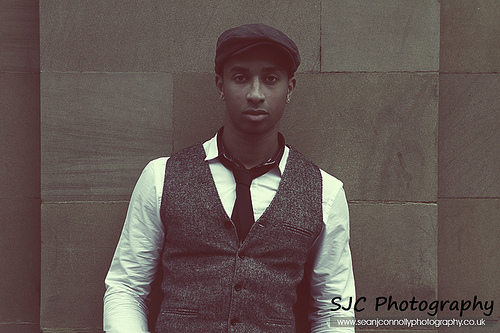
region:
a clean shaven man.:
[181, 13, 323, 163]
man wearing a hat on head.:
[195, 10, 305, 140]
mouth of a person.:
[241, 101, 268, 132]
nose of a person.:
[245, 75, 265, 105]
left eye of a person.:
[260, 70, 280, 95]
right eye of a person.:
[230, 65, 250, 86]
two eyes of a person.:
[225, 67, 285, 83]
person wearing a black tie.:
[210, 151, 285, 226]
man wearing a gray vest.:
[95, 25, 385, 325]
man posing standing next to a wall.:
[98, 7, 403, 310]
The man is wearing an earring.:
[196, 90, 250, 120]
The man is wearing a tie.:
[213, 176, 257, 208]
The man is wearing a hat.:
[201, 20, 286, 60]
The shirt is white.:
[114, 234, 158, 266]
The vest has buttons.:
[222, 281, 255, 301]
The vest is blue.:
[256, 286, 284, 304]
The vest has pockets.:
[272, 220, 321, 259]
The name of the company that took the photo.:
[314, 290, 499, 318]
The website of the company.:
[325, 317, 499, 329]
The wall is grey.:
[354, 129, 404, 171]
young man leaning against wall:
[86, 15, 377, 310]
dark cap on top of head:
[197, 12, 334, 137]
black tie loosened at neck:
[195, 107, 300, 247]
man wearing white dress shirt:
[90, 15, 382, 330]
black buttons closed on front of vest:
[210, 227, 247, 327]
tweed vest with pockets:
[140, 135, 320, 330]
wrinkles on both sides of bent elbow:
[85, 220, 155, 315]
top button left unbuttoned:
[210, 210, 272, 232]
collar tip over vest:
[185, 130, 221, 165]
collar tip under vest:
[265, 135, 295, 185]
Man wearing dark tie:
[215, 129, 280, 248]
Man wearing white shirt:
[198, 190, 398, 326]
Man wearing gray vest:
[131, 173, 298, 270]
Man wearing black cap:
[219, 23, 329, 96]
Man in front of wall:
[138, 55, 358, 316]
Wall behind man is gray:
[112, 62, 409, 235]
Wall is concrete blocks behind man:
[58, 38, 421, 274]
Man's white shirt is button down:
[136, 135, 412, 332]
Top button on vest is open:
[222, 219, 279, 251]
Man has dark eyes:
[207, 60, 292, 108]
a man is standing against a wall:
[75, 15, 400, 329]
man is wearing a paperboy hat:
[210, 26, 310, 78]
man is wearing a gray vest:
[163, 144, 305, 331]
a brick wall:
[387, 3, 488, 274]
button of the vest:
[235, 249, 250, 265]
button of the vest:
[234, 278, 245, 300]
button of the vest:
[229, 313, 243, 324]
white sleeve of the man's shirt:
[83, 163, 166, 332]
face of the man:
[216, 55, 294, 135]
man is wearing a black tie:
[215, 132, 282, 242]